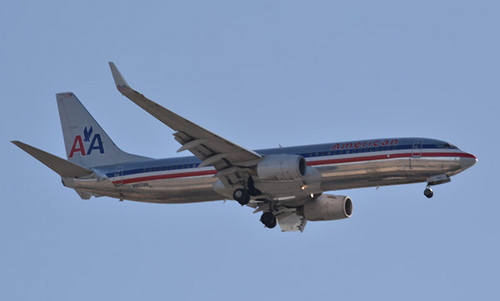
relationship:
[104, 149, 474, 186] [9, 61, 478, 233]
stripes on airplane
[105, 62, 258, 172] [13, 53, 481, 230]
wing on airplane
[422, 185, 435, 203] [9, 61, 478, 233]
front wheel on airplane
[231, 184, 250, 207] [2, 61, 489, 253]
wheel on plane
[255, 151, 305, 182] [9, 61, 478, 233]
engine on airplane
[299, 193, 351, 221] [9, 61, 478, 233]
engine on airplane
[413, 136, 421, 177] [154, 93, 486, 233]
door on plane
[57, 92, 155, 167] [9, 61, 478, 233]
tail of airplane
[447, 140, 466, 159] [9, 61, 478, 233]
cockpit of airplane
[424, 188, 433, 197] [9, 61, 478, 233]
front wheel under airplane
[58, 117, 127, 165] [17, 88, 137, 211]
logo on tail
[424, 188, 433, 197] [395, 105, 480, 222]
front wheel under cockpit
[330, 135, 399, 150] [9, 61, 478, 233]
american painted on airplane